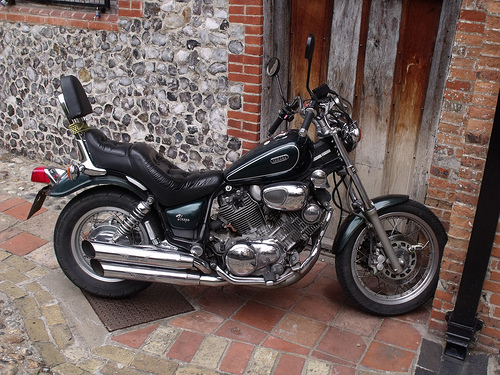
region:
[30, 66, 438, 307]
black motorcycle on brick walkway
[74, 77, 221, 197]
black cushioned seat of motorcycle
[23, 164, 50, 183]
red tail light of motorcycle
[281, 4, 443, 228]
wood door behind motorcycle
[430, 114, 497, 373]
black drainage pipe on brick wall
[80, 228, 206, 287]
muffler pipes of motorcycle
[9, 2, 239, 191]
gray stone wall behind motorcycle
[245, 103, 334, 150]
handles of the motorcycle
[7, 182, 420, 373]
brick pathway bike is parked on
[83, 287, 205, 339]
brown mat under motorcycle's back tire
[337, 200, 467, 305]
The tire is black.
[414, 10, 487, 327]
The edge is brick.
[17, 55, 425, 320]
The bike is black.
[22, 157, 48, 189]
The light is red.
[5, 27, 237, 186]
The wall is rock.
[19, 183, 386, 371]
The ground is brick.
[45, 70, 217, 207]
The seat is black.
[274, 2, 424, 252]
The door is wood.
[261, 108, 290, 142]
The handlebar is black.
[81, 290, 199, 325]
The mat is black.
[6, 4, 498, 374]
a motorcycle is parked at a door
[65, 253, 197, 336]
a door mat is under the bike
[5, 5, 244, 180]
a rock wall is on the building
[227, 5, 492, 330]
red brick is around the door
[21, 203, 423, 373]
tile is under the motorcycle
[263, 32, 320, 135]
mirrors are on the handlebars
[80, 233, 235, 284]
the exhaust pipes are chrome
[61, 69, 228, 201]
the motorcycle seat is black leather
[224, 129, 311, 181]
the gas tank is black and silver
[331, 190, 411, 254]
the front fender is black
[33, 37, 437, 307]
Silver and black motorcycle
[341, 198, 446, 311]
Front wheel of motorcycle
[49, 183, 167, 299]
Back wheel of motorcycle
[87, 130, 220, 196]
Black seat of motorcycle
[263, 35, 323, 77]
Side mirrors on motorcycle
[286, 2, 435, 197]
Brown door made of wood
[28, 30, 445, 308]
Motorcycle parked in front of building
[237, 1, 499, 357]
Building made of bricks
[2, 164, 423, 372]
Floor made of bricks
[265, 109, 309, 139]
Handles of a motorcycle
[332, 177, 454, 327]
front tire of a motorcycle.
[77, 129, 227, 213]
a seat on the back of a motorcycle.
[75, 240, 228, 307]
an exhaust on a motorcycle.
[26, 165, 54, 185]
a tail light on a motorcycle.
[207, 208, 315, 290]
an engine on a motorcycle.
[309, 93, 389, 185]
a headlight on a motorcycle.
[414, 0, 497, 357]
a pillar of bricks.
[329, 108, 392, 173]
a small chrome headlight.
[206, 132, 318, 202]
a large motorcycle fuel tank.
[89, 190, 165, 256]
a suspension device.